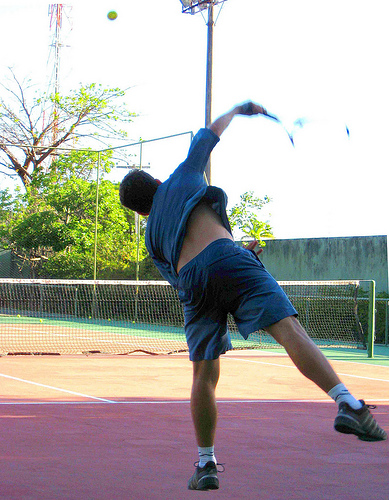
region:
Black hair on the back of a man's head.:
[116, 170, 159, 215]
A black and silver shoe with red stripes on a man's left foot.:
[185, 460, 220, 490]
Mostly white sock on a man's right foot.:
[327, 382, 363, 410]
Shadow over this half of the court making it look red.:
[0, 393, 387, 498]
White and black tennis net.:
[0, 278, 368, 358]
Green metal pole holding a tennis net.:
[366, 279, 376, 356]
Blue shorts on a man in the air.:
[171, 238, 298, 361]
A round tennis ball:
[102, 6, 120, 24]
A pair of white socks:
[192, 377, 363, 468]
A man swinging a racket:
[115, 96, 387, 495]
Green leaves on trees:
[2, 86, 272, 280]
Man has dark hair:
[115, 164, 168, 217]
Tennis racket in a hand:
[234, 94, 355, 150]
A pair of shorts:
[170, 235, 303, 363]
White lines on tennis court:
[1, 362, 386, 408]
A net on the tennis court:
[0, 274, 378, 359]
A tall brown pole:
[201, 2, 215, 190]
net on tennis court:
[1, 276, 376, 356]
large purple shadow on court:
[8, 397, 386, 498]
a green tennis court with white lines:
[5, 314, 387, 498]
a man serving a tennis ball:
[116, 102, 384, 488]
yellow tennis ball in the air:
[107, 10, 116, 21]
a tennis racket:
[246, 101, 349, 156]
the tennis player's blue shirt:
[137, 128, 231, 283]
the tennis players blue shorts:
[176, 236, 296, 359]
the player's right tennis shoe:
[335, 399, 386, 440]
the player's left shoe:
[186, 460, 218, 490]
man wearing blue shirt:
[112, 79, 352, 469]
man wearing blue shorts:
[129, 121, 379, 451]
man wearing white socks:
[119, 74, 385, 487]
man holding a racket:
[97, 76, 371, 496]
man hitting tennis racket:
[85, 88, 385, 487]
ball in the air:
[100, 3, 125, 25]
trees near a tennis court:
[26, 182, 78, 253]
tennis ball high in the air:
[88, 3, 144, 34]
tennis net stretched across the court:
[2, 270, 382, 358]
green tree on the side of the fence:
[4, 193, 147, 266]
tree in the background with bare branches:
[0, 64, 111, 158]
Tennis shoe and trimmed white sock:
[175, 430, 253, 491]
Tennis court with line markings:
[3, 305, 385, 401]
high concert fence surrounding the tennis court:
[6, 232, 387, 280]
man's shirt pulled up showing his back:
[101, 135, 283, 285]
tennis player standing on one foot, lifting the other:
[108, 162, 385, 497]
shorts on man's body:
[174, 236, 298, 361]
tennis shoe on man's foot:
[185, 461, 220, 491]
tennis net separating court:
[1, 278, 376, 359]